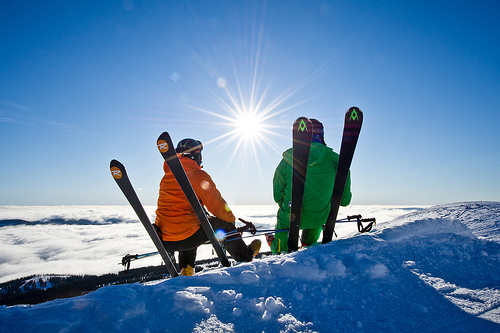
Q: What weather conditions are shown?
A: It is clear.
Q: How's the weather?
A: It is clear.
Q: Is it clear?
A: Yes, it is clear.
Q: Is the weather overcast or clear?
A: It is clear.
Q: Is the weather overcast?
A: No, it is clear.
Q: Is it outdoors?
A: Yes, it is outdoors.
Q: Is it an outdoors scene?
A: Yes, it is outdoors.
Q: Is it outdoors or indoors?
A: It is outdoors.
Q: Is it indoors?
A: No, it is outdoors.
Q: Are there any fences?
A: No, there are no fences.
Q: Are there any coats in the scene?
A: Yes, there is a coat.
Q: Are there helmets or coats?
A: Yes, there is a coat.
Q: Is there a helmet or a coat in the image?
A: Yes, there is a coat.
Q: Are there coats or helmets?
A: Yes, there is a coat.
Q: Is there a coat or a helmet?
A: Yes, there is a coat.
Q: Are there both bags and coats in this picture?
A: No, there is a coat but no bags.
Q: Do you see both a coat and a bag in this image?
A: No, there is a coat but no bags.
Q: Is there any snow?
A: Yes, there is snow.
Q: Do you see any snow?
A: Yes, there is snow.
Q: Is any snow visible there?
A: Yes, there is snow.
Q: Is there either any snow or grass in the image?
A: Yes, there is snow.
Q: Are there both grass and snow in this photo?
A: No, there is snow but no grass.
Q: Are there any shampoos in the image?
A: No, there are no shampoos.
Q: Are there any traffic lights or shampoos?
A: No, there are no shampoos or traffic lights.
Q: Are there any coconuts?
A: No, there are no coconuts.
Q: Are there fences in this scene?
A: No, there are no fences.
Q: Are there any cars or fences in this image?
A: No, there are no fences or cars.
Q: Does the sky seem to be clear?
A: Yes, the sky is clear.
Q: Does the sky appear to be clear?
A: Yes, the sky is clear.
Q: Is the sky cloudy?
A: No, the sky is clear.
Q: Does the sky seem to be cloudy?
A: No, the sky is clear.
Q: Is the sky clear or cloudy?
A: The sky is clear.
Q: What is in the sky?
A: The sun is in the sky.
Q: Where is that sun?
A: The sun is in the sky.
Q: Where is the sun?
A: The sun is in the sky.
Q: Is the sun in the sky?
A: Yes, the sun is in the sky.